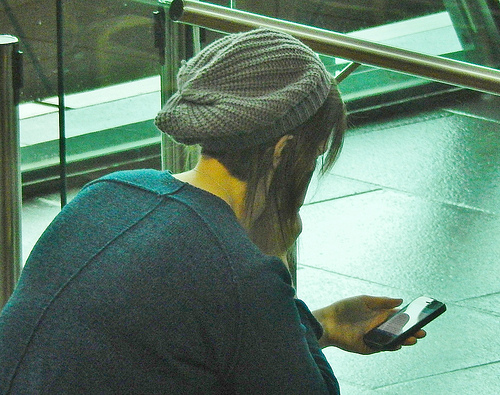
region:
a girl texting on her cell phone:
[3, 34, 445, 392]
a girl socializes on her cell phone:
[2, 31, 446, 392]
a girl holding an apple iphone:
[2, 30, 447, 393]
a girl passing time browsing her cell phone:
[0, 33, 448, 392]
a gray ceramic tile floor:
[8, 88, 490, 392]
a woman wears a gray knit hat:
[5, 32, 443, 391]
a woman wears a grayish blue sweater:
[3, 31, 423, 388]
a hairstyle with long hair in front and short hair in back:
[166, 74, 341, 256]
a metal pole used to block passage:
[0, 35, 20, 320]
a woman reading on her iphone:
[1, 32, 446, 392]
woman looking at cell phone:
[3, 24, 443, 392]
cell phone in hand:
[320, 292, 447, 353]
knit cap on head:
[160, 30, 329, 148]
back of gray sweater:
[4, 165, 330, 393]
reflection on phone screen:
[384, 298, 431, 340]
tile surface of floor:
[28, 104, 493, 393]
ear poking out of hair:
[268, 132, 294, 170]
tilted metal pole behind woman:
[173, 3, 498, 96]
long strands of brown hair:
[242, 140, 320, 256]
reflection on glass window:
[10, 2, 475, 143]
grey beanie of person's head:
[155, 22, 352, 158]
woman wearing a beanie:
[148, 3, 335, 152]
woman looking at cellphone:
[360, 275, 453, 384]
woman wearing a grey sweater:
[1, 105, 366, 393]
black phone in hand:
[340, 253, 468, 368]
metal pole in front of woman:
[180, 0, 498, 124]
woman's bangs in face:
[302, 75, 357, 188]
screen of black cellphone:
[379, 291, 436, 353]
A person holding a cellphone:
[295, 259, 454, 381]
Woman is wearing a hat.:
[161, 37, 343, 149]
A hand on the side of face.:
[248, 140, 314, 257]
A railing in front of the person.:
[180, 4, 481, 108]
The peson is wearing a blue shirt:
[52, 232, 294, 381]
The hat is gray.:
[160, 46, 301, 134]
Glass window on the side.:
[33, 19, 158, 126]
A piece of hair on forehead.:
[327, 101, 353, 183]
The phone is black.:
[372, 289, 449, 359]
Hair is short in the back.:
[194, 140, 264, 180]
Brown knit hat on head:
[152, 25, 329, 138]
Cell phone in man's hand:
[363, 292, 444, 349]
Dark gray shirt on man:
[3, 168, 334, 393]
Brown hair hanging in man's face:
[323, 110, 348, 174]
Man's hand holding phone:
[329, 296, 424, 346]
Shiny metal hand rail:
[171, 3, 498, 95]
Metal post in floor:
[0, 34, 20, 296]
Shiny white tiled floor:
[289, 115, 494, 393]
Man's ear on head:
[270, 135, 293, 161]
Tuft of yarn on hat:
[177, 55, 190, 68]